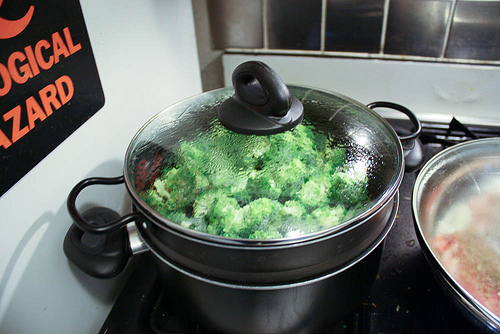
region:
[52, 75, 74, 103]
a letter is written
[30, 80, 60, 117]
a letter is written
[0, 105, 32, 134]
a letter is written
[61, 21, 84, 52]
a letter is written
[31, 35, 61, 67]
a letter is written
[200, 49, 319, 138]
Black plastic holder of a pot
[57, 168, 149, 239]
A black rounded pot handle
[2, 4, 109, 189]
A black sign with partial words on it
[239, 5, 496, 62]
A black tile backsplash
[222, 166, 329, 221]
Some broccoli steaming in a pot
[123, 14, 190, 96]
A part of a blank white wall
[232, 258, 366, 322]
Side of a silver cooking pot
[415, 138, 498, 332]
A cooking piece on a stovetop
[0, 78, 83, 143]
The letters ZARD in red on black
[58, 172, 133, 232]
A handle on a pot lid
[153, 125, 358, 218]
Vegetables inside a pot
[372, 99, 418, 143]
A handle on a pot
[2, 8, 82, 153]
Orange letters on a black sign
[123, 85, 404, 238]
A glass pot lid on a pot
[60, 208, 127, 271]
A black handle on a lid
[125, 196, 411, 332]
A metal pot under another pot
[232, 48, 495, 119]
White trim on a wall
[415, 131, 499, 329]
A glass lid on a pot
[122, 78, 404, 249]
steamed broccoli in a double boiler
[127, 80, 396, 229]
steam collected on the bottom of a glass lid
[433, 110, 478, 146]
control for the range top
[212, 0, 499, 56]
reflecting tiles along the wall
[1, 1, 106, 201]
neon orange print on a black background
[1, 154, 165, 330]
shadow of cookware on the wall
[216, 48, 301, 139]
black handle of a glass lid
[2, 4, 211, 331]
a white wall by the stove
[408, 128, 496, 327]
glass covered fry pan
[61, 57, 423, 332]
a double boiler on the back burner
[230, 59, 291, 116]
A black handle on a large pot.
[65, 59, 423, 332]
A very large steamer pot with black handle lid.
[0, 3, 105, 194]
A black and orange sign.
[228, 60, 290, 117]
A black handle on top of a broccoli pot.